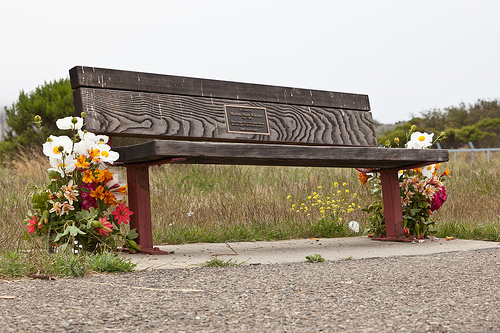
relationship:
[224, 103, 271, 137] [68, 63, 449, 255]
plaque on bench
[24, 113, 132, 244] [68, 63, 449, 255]
flower on side of bench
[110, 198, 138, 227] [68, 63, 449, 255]
flower on side of bench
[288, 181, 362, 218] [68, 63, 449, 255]
flower growing underneath bench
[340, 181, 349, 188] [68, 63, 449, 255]
flower growing underneath bench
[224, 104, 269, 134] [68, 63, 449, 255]
plaque mounted on bench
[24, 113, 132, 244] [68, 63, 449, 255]
flower at end bench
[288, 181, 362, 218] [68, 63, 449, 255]
flower at end bench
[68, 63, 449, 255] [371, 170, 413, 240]
bench on leg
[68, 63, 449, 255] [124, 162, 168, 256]
bench on leg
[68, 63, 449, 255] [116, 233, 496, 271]
bench sitting on pad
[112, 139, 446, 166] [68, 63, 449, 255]
seat of bench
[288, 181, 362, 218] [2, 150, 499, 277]
flower growing in grass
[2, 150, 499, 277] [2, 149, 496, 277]
grass growing in field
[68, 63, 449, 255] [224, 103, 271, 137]
bench with plaque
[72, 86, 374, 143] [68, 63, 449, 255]
slat of bench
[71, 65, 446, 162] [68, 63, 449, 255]
slat forming bench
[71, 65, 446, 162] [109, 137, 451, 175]
slat forming bench seat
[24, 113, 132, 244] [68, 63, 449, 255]
flower blooming next to bench